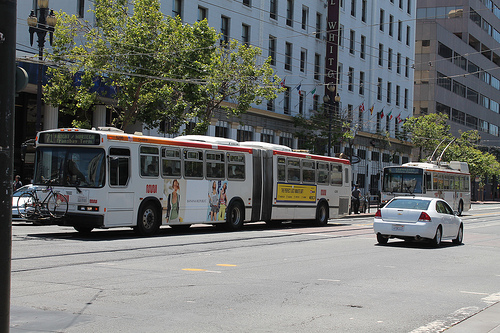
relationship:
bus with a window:
[33, 128, 351, 232] [181, 144, 201, 180]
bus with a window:
[33, 128, 351, 232] [204, 150, 224, 180]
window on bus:
[160, 145, 183, 179] [33, 128, 351, 232]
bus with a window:
[33, 128, 351, 232] [227, 151, 246, 182]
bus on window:
[33, 128, 351, 232] [106, 146, 132, 187]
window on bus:
[139, 146, 160, 177] [33, 128, 351, 232]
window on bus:
[227, 151, 246, 182] [33, 128, 351, 232]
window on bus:
[204, 150, 224, 180] [33, 128, 351, 232]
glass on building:
[198, 8, 208, 33] [0, 1, 418, 203]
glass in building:
[198, 8, 208, 33] [0, 1, 418, 203]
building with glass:
[0, 1, 418, 203] [198, 8, 208, 33]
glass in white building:
[198, 8, 208, 33] [0, 1, 418, 203]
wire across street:
[4, 42, 495, 87] [181, 202, 498, 333]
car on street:
[373, 194, 468, 248] [181, 202, 498, 333]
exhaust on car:
[413, 232, 420, 244] [373, 194, 468, 248]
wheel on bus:
[135, 199, 163, 236] [33, 128, 351, 232]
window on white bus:
[181, 144, 201, 180] [33, 128, 351, 232]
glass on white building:
[198, 8, 208, 33] [0, 1, 418, 203]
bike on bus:
[17, 173, 71, 225] [33, 128, 351, 232]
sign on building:
[325, 0, 338, 111] [0, 1, 418, 203]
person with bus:
[352, 181, 360, 209] [33, 128, 351, 232]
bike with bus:
[17, 173, 71, 225] [33, 128, 351, 232]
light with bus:
[86, 204, 94, 214] [33, 128, 351, 232]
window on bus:
[106, 146, 132, 187] [33, 128, 351, 232]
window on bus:
[181, 144, 201, 180] [33, 128, 351, 232]